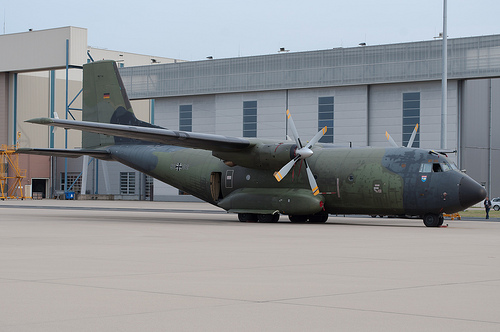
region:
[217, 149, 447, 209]
An airforce plane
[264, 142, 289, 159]
The plane engine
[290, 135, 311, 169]
The propeller of the plane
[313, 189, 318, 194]
Stripes on tip of blade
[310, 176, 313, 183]
The plane's propeller blade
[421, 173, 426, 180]
Flag painted under cockpit window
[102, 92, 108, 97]
Flag painted on the tail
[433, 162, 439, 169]
The cockpit window open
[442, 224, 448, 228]
The wheel stopper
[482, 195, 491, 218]
A person standing next to the plane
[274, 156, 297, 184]
propeller on cargo plane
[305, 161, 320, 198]
propeller on cargo plane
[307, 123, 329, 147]
propeller on cargo plane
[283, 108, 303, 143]
propeller on cargo plane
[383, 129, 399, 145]
propeller on cargo plane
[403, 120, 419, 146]
propeller on cargo plane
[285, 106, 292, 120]
orange stripes on propeller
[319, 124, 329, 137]
orange stripes on propeller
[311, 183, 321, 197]
orange stripes on propeller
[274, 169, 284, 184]
orange stripes on propeller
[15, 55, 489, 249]
green airplane on tarmac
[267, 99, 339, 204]
grey and orange propellar on front of plane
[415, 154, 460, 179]
windshield on front of plane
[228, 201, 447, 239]
black tires on bottom of plane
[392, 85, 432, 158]
window on side of building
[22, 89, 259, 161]
wing on side of plane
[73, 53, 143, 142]
green tail on plane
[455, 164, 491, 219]
black nose on front of plane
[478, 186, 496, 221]
person walking on tarmac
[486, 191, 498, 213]
white car parked on side of building